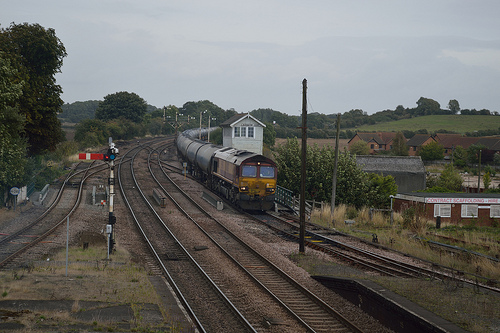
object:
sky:
[2, 2, 497, 114]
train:
[170, 124, 283, 215]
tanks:
[192, 142, 222, 183]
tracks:
[109, 160, 264, 333]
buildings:
[388, 188, 497, 229]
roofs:
[346, 128, 399, 145]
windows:
[233, 126, 240, 138]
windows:
[487, 204, 500, 218]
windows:
[257, 165, 275, 178]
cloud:
[27, 3, 499, 117]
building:
[219, 112, 269, 159]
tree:
[1, 27, 35, 205]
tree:
[2, 20, 66, 160]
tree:
[77, 132, 98, 149]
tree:
[97, 90, 148, 130]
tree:
[117, 117, 135, 138]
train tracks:
[141, 156, 211, 332]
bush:
[274, 137, 393, 214]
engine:
[219, 153, 280, 215]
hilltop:
[346, 111, 500, 136]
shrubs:
[364, 115, 380, 122]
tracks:
[0, 167, 96, 268]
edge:
[12, 124, 163, 206]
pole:
[199, 109, 203, 141]